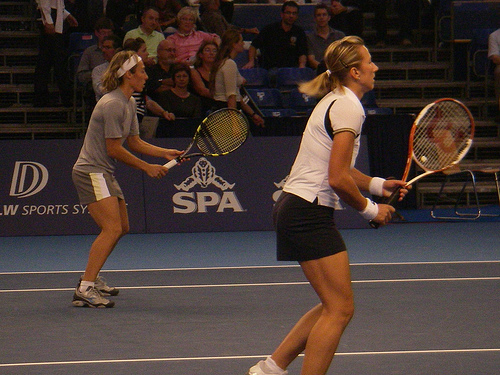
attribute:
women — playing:
[37, 12, 423, 367]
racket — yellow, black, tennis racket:
[180, 109, 334, 191]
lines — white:
[8, 265, 497, 353]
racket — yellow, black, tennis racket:
[156, 98, 243, 177]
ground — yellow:
[413, 172, 458, 215]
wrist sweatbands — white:
[356, 175, 387, 221]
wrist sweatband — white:
[368, 176, 386, 197]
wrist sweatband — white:
[356, 196, 378, 221]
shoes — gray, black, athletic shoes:
[65, 277, 121, 315]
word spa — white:
[168, 182, 248, 219]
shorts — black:
[267, 191, 348, 263]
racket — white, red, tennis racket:
[393, 93, 488, 205]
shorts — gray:
[63, 162, 152, 212]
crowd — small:
[96, 15, 297, 134]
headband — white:
[113, 56, 134, 76]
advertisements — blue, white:
[168, 159, 250, 224]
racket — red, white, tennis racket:
[366, 95, 478, 232]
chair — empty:
[422, 154, 499, 221]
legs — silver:
[426, 168, 498, 219]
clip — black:
[338, 58, 351, 68]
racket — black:
[155, 104, 248, 174]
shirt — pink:
[157, 27, 217, 67]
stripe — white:
[85, 170, 111, 201]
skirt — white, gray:
[67, 165, 125, 205]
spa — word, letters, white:
[173, 187, 243, 214]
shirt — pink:
[160, 28, 221, 63]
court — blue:
[2, 207, 499, 371]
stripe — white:
[87, 167, 111, 206]